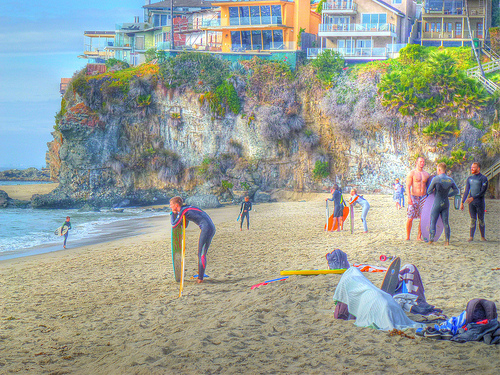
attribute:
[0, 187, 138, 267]
water — blue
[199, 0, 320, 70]
house — yellow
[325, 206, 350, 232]
surfboard — red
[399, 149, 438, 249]
man — swim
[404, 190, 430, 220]
trunks — multi-colored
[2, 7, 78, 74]
sky — blue, cloudy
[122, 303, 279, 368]
sand — brown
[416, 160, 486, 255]
man — boogie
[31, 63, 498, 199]
cliff — rocky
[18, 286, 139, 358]
sand — tanned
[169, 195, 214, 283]
man — with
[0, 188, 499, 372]
beach — sandy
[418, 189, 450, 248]
board — purple